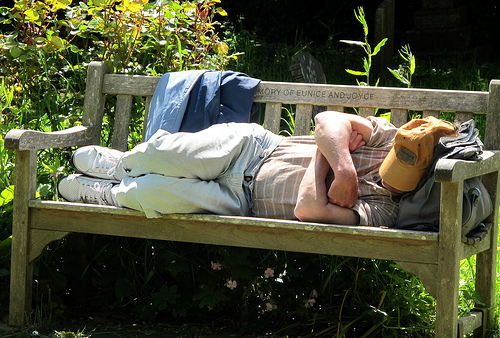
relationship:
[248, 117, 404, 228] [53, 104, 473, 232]
shirt on man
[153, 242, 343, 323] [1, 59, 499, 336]
flowers under bench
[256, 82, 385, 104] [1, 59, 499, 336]
writing on bench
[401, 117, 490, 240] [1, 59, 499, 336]
bag on bench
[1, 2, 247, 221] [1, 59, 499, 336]
bush next to bench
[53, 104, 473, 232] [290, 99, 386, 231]
man has arms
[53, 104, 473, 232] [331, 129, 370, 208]
man has hands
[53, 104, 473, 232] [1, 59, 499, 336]
man laying on bench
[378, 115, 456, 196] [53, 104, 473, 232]
hat worn by man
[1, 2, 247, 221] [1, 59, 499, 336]
bush behind bench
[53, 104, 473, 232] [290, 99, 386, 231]
man crossing arms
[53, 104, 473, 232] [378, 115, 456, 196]
man wearing hat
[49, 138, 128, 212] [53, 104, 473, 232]
shoes worn by man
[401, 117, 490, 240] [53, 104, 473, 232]
bag under man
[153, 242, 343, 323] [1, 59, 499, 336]
flowers are under bench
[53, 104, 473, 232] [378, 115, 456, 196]
man wearing yellow hat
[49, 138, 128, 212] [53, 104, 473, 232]
shoes on man